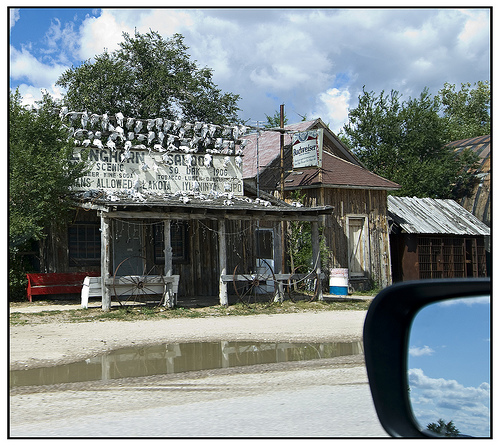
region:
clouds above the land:
[261, 27, 346, 82]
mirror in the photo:
[365, 236, 495, 431]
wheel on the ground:
[222, 255, 282, 311]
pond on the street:
[151, 330, 227, 385]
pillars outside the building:
[85, 231, 250, 271]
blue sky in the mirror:
[425, 326, 476, 367]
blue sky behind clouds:
[23, 15, 52, 33]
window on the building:
[67, 223, 114, 260]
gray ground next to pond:
[204, 378, 336, 430]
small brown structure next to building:
[388, 185, 480, 281]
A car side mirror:
[362, 277, 499, 442]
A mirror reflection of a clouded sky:
[409, 295, 499, 438]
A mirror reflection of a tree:
[424, 414, 460, 436]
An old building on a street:
[26, 107, 397, 312]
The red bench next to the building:
[24, 269, 100, 302]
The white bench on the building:
[79, 274, 179, 309]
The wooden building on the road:
[27, 104, 499, 310]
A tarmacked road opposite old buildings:
[3, 311, 373, 442]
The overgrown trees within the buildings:
[7, 24, 493, 322]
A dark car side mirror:
[360, 264, 492, 445]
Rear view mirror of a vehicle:
[362, 272, 487, 434]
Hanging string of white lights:
[107, 215, 261, 248]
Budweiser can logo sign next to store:
[288, 128, 323, 170]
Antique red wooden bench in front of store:
[26, 270, 100, 300]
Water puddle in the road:
[10, 334, 365, 391]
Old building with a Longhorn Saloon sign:
[27, 142, 333, 309]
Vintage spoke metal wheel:
[112, 252, 168, 316]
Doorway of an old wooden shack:
[343, 214, 369, 279]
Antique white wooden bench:
[79, 275, 179, 309]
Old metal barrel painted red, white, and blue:
[327, 265, 350, 302]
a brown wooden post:
[274, 98, 296, 300]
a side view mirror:
[358, 273, 490, 438]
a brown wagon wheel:
[226, 250, 281, 314]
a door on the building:
[341, 210, 376, 285]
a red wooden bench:
[21, 266, 118, 305]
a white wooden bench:
[76, 269, 190, 311]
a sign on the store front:
[56, 146, 251, 198]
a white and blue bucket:
[323, 263, 352, 297]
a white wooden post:
[214, 217, 235, 312]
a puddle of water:
[8, 325, 365, 402]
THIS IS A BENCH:
[19, 264, 106, 305]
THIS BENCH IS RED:
[21, 268, 103, 307]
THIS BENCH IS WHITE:
[76, 270, 191, 309]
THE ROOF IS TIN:
[375, 190, 495, 247]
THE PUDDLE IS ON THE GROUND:
[8, 318, 368, 398]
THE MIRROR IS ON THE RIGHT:
[357, 270, 492, 439]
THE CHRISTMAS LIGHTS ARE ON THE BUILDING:
[98, 204, 327, 253]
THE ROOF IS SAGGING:
[77, 175, 337, 225]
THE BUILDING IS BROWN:
[384, 225, 487, 291]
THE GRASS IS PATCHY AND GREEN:
[5, 266, 390, 331]